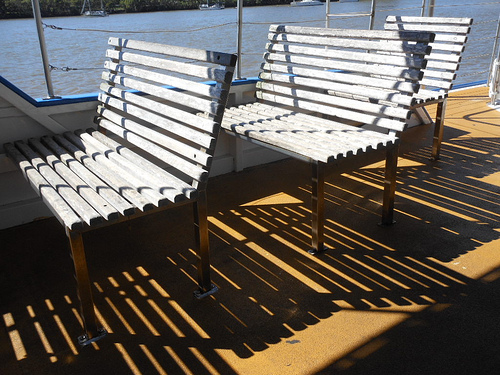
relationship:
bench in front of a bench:
[3, 36, 237, 343] [191, 24, 435, 256]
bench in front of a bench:
[3, 36, 237, 343] [323, 14, 473, 161]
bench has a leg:
[3, 36, 237, 343] [64, 226, 106, 343]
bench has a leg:
[3, 36, 237, 343] [192, 189, 217, 296]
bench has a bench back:
[3, 36, 237, 343] [93, 36, 238, 190]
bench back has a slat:
[93, 36, 238, 190] [99, 82, 207, 137]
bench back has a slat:
[93, 36, 238, 190] [99, 82, 220, 135]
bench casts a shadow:
[3, 36, 237, 343] [93, 202, 500, 358]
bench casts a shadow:
[191, 24, 435, 256] [282, 165, 500, 263]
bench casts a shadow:
[323, 14, 473, 161] [394, 137, 499, 192]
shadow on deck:
[93, 202, 500, 358] [1, 86, 500, 375]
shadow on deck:
[282, 165, 500, 263] [1, 86, 500, 375]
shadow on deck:
[394, 137, 499, 192] [1, 86, 500, 375]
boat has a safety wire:
[0, 0, 499, 375] [42, 21, 238, 34]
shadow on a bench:
[231, 25, 436, 137] [191, 24, 435, 256]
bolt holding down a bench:
[79, 335, 86, 340] [3, 36, 237, 343]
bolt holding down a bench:
[98, 328, 105, 333] [3, 36, 237, 343]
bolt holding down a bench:
[196, 289, 202, 294] [3, 36, 237, 343]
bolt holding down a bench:
[211, 283, 215, 287] [3, 36, 237, 343]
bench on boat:
[3, 36, 237, 343] [0, 0, 499, 375]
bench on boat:
[191, 24, 435, 256] [0, 0, 499, 375]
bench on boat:
[323, 14, 473, 161] [0, 0, 499, 375]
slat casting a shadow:
[99, 82, 207, 137] [281, 205, 477, 306]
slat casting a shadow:
[99, 82, 207, 137] [286, 205, 478, 295]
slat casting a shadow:
[99, 82, 207, 137] [273, 205, 471, 303]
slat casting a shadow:
[99, 82, 207, 137] [257, 206, 458, 304]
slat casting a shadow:
[99, 82, 220, 135] [245, 207, 433, 305]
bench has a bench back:
[191, 24, 435, 256] [253, 24, 435, 137]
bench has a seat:
[3, 36, 237, 343] [3, 127, 198, 231]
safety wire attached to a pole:
[42, 21, 238, 34] [31, 0, 62, 101]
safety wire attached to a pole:
[47, 52, 237, 72] [31, 0, 62, 101]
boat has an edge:
[0, 0, 499, 375] [0, 69, 487, 108]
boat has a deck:
[0, 0, 499, 375] [1, 86, 500, 375]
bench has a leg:
[191, 24, 435, 256] [308, 159, 329, 255]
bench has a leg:
[191, 24, 435, 256] [377, 146, 399, 229]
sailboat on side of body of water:
[79, 0, 110, 17] [0, 0, 499, 99]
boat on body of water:
[290, 0, 325, 7] [0, 0, 499, 99]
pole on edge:
[234, 1, 247, 82] [0, 69, 487, 108]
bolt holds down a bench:
[309, 248, 316, 253] [191, 24, 435, 256]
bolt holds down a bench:
[322, 245, 326, 248] [191, 24, 435, 256]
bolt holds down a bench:
[379, 222, 384, 225] [191, 24, 435, 256]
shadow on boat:
[93, 202, 500, 358] [0, 0, 499, 375]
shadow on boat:
[282, 165, 500, 263] [0, 0, 499, 375]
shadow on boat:
[394, 137, 499, 192] [0, 0, 499, 375]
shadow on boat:
[281, 205, 477, 306] [0, 0, 499, 375]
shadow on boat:
[286, 205, 478, 295] [0, 0, 499, 375]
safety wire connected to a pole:
[242, 13, 371, 24] [234, 1, 247, 82]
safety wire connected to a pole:
[242, 13, 371, 24] [364, 0, 376, 65]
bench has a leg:
[323, 14, 473, 161] [427, 98, 447, 162]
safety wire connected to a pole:
[240, 46, 347, 56] [234, 1, 247, 82]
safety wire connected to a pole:
[240, 46, 347, 56] [364, 0, 376, 65]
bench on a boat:
[3, 36, 237, 343] [0, 0, 499, 375]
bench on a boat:
[191, 24, 435, 256] [0, 0, 499, 375]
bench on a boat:
[323, 14, 473, 161] [0, 0, 499, 375]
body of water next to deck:
[0, 0, 499, 99] [1, 86, 500, 375]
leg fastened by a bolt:
[64, 226, 106, 343] [79, 335, 86, 340]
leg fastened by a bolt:
[64, 226, 106, 343] [98, 328, 105, 333]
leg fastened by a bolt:
[192, 189, 217, 296] [196, 289, 202, 294]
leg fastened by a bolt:
[192, 189, 217, 296] [211, 283, 215, 287]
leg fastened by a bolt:
[308, 159, 329, 255] [309, 248, 316, 253]